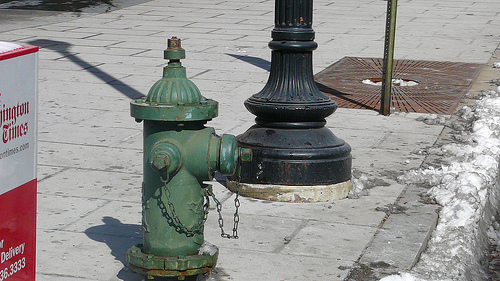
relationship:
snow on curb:
[381, 58, 500, 281] [401, 91, 499, 280]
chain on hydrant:
[159, 162, 243, 241] [129, 35, 256, 280]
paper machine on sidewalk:
[1, 39, 36, 280] [1, 1, 500, 280]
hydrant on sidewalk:
[129, 35, 256, 280] [1, 1, 500, 280]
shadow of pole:
[28, 35, 237, 157] [223, 1, 356, 204]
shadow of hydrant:
[84, 213, 150, 281] [129, 35, 256, 280]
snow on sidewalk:
[381, 58, 500, 281] [1, 1, 500, 280]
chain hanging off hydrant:
[159, 162, 243, 241] [129, 35, 256, 280]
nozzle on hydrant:
[165, 35, 182, 51] [129, 35, 256, 280]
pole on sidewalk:
[379, 2, 397, 119] [1, 1, 500, 280]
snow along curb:
[381, 58, 500, 281] [401, 91, 499, 280]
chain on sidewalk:
[159, 162, 243, 241] [1, 1, 500, 280]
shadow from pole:
[28, 35, 237, 157] [223, 1, 356, 204]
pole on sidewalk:
[223, 1, 356, 204] [1, 1, 500, 280]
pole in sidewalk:
[223, 1, 356, 204] [1, 1, 500, 280]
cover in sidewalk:
[304, 55, 486, 121] [1, 1, 500, 280]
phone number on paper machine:
[1, 256, 27, 281] [1, 39, 36, 280]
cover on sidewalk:
[304, 55, 486, 121] [1, 1, 500, 280]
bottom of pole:
[222, 119, 356, 187] [223, 1, 356, 204]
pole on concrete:
[223, 1, 356, 204] [225, 175, 353, 203]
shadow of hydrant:
[28, 35, 237, 157] [129, 35, 256, 280]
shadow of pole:
[227, 52, 384, 114] [379, 2, 397, 119]